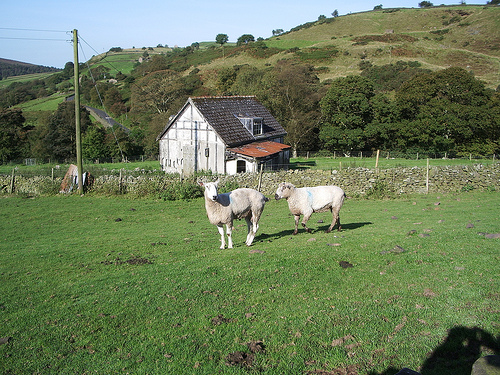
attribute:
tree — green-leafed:
[392, 64, 483, 156]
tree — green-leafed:
[371, 62, 404, 93]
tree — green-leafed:
[364, 90, 404, 155]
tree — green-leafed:
[314, 71, 379, 158]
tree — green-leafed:
[257, 74, 288, 125]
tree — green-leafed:
[226, 68, 261, 98]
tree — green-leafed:
[119, 111, 152, 155]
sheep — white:
[265, 175, 354, 231]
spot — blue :
[299, 182, 324, 214]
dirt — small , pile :
[212, 342, 264, 367]